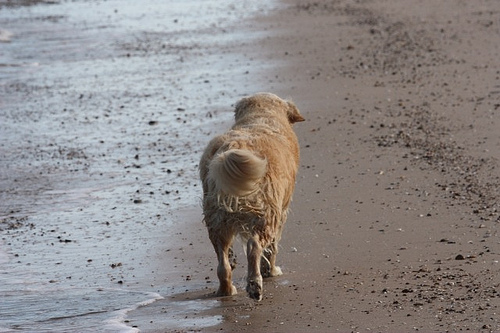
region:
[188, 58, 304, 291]
dog on the sand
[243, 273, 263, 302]
paw of the dog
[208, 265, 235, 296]
paw of the dog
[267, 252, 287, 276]
paw of te dog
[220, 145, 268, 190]
tail of the dog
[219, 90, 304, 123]
head of the dog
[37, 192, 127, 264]
the sand is wet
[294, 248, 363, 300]
sand on the beach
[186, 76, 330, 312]
a medium sized dog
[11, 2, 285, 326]
water coming up on the beach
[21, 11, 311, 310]
ocean water coming up on the sand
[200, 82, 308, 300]
a shaggy tan dog that is wet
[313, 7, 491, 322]
rocks in the sand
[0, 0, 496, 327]
a ground made of sand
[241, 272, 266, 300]
a dog paw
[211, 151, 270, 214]
a tan dog tail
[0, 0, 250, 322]
water line at the beach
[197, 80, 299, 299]
a dog walking on the beach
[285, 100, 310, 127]
a tan dog's ear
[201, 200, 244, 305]
a tan dogs leg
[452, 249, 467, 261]
a little black rock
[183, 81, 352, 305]
dog walking on the beach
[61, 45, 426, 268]
wet sandy beach and a dog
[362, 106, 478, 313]
rocks on a beach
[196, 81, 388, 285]
dog waling in the sand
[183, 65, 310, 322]
dog walking on sandy beach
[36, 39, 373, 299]
wet sandy beach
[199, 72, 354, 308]
dog with white tail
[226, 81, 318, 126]
ears on a dog